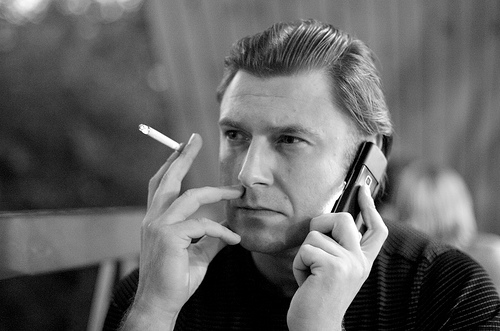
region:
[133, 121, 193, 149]
A lit white cigarrate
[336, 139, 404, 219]
A black And grey mobile phone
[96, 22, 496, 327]
A man talking on phone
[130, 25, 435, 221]
A man talking on phone's head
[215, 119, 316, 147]
A man talking on phone's eyes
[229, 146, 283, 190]
A man talking on phone's nose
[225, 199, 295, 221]
A man talking on phone's nose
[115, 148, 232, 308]
A man talking on phone's hand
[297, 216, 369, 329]
A man talking on phone's hand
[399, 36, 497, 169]
A white photo background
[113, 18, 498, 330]
man with phone to head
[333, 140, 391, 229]
back of cell phone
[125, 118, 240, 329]
cigarette in man's hand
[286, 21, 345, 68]
comb marks in hair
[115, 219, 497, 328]
pattern on dark shirt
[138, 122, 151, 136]
ash on end of cigarette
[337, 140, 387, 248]
finger on back of phone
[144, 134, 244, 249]
fingers on man's hand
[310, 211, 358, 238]
knuckle of bent finger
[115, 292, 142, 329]
hair on man's wrist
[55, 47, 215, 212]
the man is holding a cigarette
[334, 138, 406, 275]
the man is holding a phone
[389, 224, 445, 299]
the man is wearing a striped shirt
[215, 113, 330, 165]
the man has dark eyes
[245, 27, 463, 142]
the man has gray hair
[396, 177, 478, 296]
a woman is behind the man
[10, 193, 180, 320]
a chair is behind the man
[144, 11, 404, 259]
a curtain is behind the man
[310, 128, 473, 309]
the phone is black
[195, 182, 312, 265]
the man's finger is on his lip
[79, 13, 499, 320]
a person smiking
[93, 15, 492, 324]
a person on the phone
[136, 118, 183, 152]
a cigarette on the fingers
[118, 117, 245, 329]
a hand holding a cigarette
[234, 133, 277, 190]
a nose of the person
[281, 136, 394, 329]
a hand with a cellphone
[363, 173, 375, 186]
a built in camera of the cellphone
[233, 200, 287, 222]
a mouth of the person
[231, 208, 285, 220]
a lower lip of the person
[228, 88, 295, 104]
a wrinkle on the forehead of the person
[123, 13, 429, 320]
the man is holding a cigarette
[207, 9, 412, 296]
the man is on a cell phone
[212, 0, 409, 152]
he wears his hair slicked back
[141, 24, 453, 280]
the man appears thoughtful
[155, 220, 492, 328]
he is dressed in a darl shirt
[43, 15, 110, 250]
the background is out of focus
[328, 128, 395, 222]
the cell phone is black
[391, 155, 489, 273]
it appears there is a blonde haired person behind him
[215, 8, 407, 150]
the man has light colored hair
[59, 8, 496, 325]
a simple black & white photo